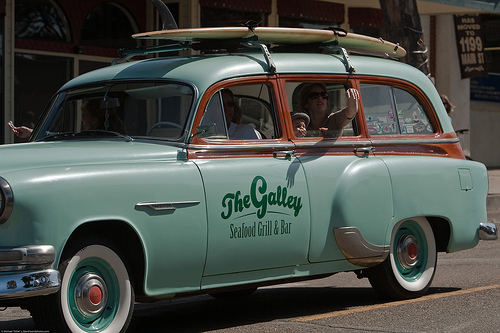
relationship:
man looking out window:
[213, 89, 259, 139] [222, 80, 278, 140]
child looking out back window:
[293, 109, 312, 137] [192, 75, 443, 141]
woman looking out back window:
[297, 79, 359, 135] [192, 75, 443, 141]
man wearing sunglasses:
[213, 89, 259, 139] [224, 98, 234, 110]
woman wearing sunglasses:
[297, 79, 359, 135] [308, 90, 328, 99]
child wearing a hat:
[293, 109, 312, 137] [292, 110, 312, 121]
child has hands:
[293, 109, 312, 137] [296, 125, 328, 134]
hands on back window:
[296, 125, 328, 134] [192, 75, 443, 141]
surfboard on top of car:
[133, 21, 407, 67] [1, 63, 499, 333]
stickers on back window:
[371, 109, 422, 134] [337, 85, 429, 140]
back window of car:
[192, 75, 443, 141] [1, 63, 499, 333]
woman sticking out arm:
[297, 79, 359, 135] [332, 90, 360, 128]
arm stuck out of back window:
[332, 90, 360, 128] [192, 75, 443, 141]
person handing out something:
[12, 102, 113, 146] [5, 121, 20, 136]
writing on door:
[220, 178, 301, 247] [193, 84, 314, 274]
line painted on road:
[298, 273, 495, 331] [3, 249, 497, 331]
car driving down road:
[1, 63, 499, 333] [3, 249, 497, 331]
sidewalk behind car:
[481, 166, 500, 208] [1, 63, 499, 333]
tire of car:
[61, 242, 136, 333] [1, 63, 499, 333]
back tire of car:
[373, 218, 437, 297] [1, 63, 499, 333]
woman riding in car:
[297, 79, 359, 135] [1, 63, 499, 333]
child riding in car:
[293, 109, 312, 137] [1, 63, 499, 333]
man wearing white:
[213, 89, 259, 139] [220, 120, 260, 143]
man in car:
[213, 89, 259, 139] [1, 63, 499, 333]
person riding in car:
[12, 102, 113, 146] [1, 63, 499, 333]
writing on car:
[220, 178, 301, 247] [1, 63, 499, 333]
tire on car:
[61, 242, 136, 333] [1, 63, 499, 333]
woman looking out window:
[297, 79, 359, 135] [222, 80, 278, 140]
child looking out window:
[293, 109, 312, 137] [222, 80, 278, 140]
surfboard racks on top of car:
[122, 44, 362, 74] [1, 63, 499, 333]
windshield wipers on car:
[42, 124, 130, 146] [1, 63, 499, 333]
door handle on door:
[274, 149, 294, 161] [193, 84, 314, 274]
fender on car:
[336, 231, 386, 269] [1, 63, 499, 333]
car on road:
[1, 63, 499, 333] [3, 249, 497, 331]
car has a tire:
[1, 63, 499, 333] [61, 242, 136, 333]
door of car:
[193, 84, 314, 274] [1, 63, 499, 333]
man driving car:
[213, 89, 259, 139] [1, 63, 499, 333]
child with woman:
[293, 109, 312, 137] [297, 79, 359, 135]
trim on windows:
[183, 75, 463, 159] [206, 79, 430, 139]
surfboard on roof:
[133, 21, 407, 67] [63, 49, 438, 93]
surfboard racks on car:
[122, 44, 362, 74] [1, 63, 499, 333]